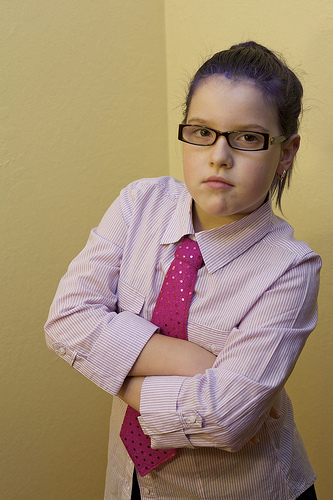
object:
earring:
[275, 167, 286, 179]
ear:
[276, 132, 300, 175]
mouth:
[200, 174, 235, 189]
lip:
[204, 181, 232, 188]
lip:
[204, 175, 231, 184]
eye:
[237, 133, 258, 144]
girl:
[42, 40, 324, 499]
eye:
[192, 125, 209, 135]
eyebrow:
[237, 123, 270, 132]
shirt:
[39, 171, 319, 499]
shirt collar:
[159, 186, 273, 274]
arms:
[43, 201, 213, 386]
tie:
[119, 236, 204, 479]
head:
[178, 40, 304, 219]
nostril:
[219, 161, 229, 168]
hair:
[181, 42, 308, 220]